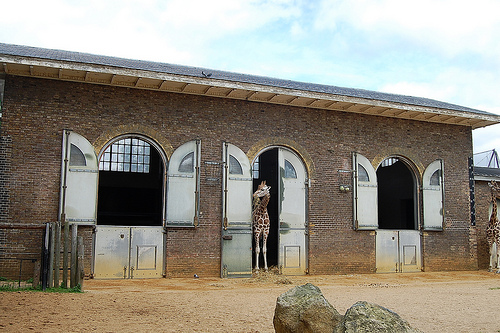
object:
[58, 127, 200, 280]
stable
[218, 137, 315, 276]
stable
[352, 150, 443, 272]
stable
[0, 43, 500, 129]
roof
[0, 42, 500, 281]
building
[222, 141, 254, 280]
door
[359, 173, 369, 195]
ground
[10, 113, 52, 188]
wall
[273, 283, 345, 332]
rock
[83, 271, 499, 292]
door step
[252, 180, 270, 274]
giraffe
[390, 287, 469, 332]
dirt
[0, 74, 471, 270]
brick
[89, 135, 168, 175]
window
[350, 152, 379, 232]
door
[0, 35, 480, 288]
stable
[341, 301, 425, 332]
rock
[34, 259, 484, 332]
dirt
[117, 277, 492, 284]
floor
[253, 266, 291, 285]
dirt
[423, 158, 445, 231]
half door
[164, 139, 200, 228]
half door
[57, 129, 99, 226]
half door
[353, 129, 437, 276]
open stable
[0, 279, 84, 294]
grass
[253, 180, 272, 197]
head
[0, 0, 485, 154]
sky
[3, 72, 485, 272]
wall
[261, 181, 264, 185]
horns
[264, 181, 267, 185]
horns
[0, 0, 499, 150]
clouds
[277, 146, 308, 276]
doors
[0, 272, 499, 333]
area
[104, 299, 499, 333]
ground